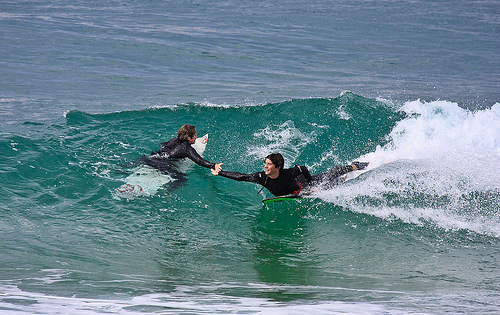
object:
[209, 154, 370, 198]
surfer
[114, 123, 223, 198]
surfer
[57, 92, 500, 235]
wave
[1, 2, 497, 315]
water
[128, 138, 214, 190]
wet suit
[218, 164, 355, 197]
wet suit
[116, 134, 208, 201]
board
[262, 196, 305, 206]
board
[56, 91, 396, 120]
crest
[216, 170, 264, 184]
arm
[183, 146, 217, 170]
arm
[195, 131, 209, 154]
nose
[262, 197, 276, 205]
nose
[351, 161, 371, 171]
foot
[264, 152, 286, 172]
cap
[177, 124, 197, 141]
hair